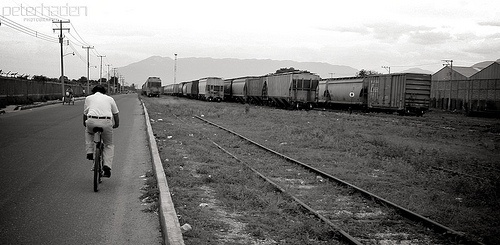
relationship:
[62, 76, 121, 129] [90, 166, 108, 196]
man riding bicycle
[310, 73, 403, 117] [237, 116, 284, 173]
train on rail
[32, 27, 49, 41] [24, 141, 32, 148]
lines on road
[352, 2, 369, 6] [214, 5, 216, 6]
clouds in sky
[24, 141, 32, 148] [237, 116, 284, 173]
road separate from rail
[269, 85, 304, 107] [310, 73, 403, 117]
engine of train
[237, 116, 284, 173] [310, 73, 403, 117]
rail for train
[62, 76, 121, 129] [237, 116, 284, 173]
man near rail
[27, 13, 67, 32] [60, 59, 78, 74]
wires between pole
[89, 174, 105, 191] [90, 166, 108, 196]
tire of bicycle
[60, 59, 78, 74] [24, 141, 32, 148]
pole near road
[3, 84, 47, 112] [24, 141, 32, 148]
fence near road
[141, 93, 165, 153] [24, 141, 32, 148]
curb divides road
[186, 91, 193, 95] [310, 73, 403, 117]
car of train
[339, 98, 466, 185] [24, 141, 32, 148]
litter on road